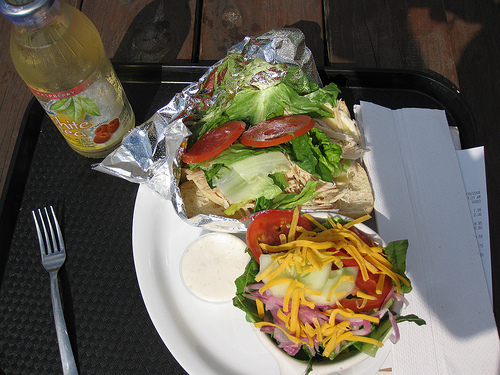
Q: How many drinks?
A: One.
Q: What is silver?
A: Fork.